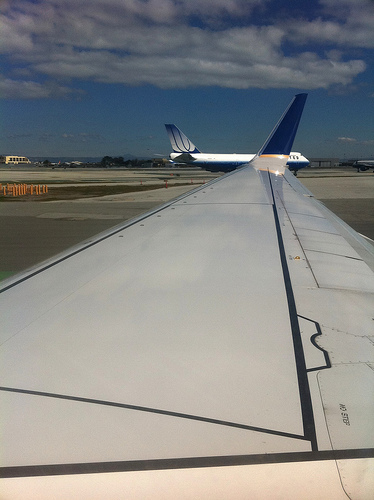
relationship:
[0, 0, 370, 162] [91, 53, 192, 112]
sky seen section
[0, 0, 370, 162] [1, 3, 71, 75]
sky seen section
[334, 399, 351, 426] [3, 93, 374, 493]
words on plane wing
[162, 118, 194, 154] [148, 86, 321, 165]
tail on plane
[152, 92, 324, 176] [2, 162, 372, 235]
airplane on tarmac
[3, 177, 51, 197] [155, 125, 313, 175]
poles by plane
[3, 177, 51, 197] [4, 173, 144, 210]
poles in ground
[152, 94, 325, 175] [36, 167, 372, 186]
airplane on runway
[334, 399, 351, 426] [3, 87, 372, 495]
words on plane wing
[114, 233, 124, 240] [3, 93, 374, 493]
bolt on plane wing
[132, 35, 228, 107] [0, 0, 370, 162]
section of sky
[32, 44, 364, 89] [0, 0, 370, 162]
cloud in sky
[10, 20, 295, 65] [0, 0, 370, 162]
cloud in sky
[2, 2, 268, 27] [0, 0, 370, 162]
cloud in sky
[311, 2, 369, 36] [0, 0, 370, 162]
cloud in sky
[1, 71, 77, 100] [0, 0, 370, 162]
cloud in sky